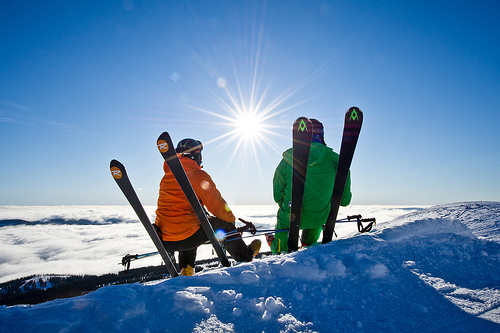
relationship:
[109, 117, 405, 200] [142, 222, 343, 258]
two skiiers sitting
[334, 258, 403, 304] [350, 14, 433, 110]
winter sun sky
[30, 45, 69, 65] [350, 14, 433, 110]
blue clear sky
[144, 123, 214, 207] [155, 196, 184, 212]
skiier wearing orange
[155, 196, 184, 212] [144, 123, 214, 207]
orange parka skiier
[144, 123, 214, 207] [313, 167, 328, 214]
skiier wearing green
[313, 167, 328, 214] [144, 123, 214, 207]
green parka skiier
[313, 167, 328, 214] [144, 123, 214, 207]
green pants skiier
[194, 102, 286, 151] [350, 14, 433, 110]
sun in sky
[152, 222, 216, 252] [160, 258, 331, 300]
sitting sitting down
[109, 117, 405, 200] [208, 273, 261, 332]
two skiiers snow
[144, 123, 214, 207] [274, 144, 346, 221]
skiier wearing coat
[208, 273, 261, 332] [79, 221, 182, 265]
snow on ground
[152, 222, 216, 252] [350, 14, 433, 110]
sitting look sky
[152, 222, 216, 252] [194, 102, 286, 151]
sitting by sun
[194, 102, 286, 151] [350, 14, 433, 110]
sun blue sky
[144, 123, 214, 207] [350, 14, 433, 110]
skiier blue sky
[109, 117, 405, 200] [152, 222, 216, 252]
two sitting sitting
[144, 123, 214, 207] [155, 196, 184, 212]
skiier in orange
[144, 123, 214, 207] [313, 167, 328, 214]
skiier in green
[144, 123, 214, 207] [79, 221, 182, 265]
skiier on ground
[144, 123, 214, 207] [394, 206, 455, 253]
skiier on mountain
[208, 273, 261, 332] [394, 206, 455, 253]
snow on mountain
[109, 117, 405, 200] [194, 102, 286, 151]
two skiiers sun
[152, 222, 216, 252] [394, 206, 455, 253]
sitting sitting mountain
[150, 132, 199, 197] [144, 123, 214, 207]
black ski skiier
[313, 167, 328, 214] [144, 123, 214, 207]
green logo skiier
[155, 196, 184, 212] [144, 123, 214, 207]
orange logo skiier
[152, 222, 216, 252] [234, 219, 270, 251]
sitting ski poles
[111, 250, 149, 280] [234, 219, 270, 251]
bands ski poles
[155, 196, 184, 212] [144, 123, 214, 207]
orange jacker skiier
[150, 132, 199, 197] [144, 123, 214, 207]
black helmet skiier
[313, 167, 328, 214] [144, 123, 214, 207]
green jacket skiier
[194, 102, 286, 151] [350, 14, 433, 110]
sun shining sky